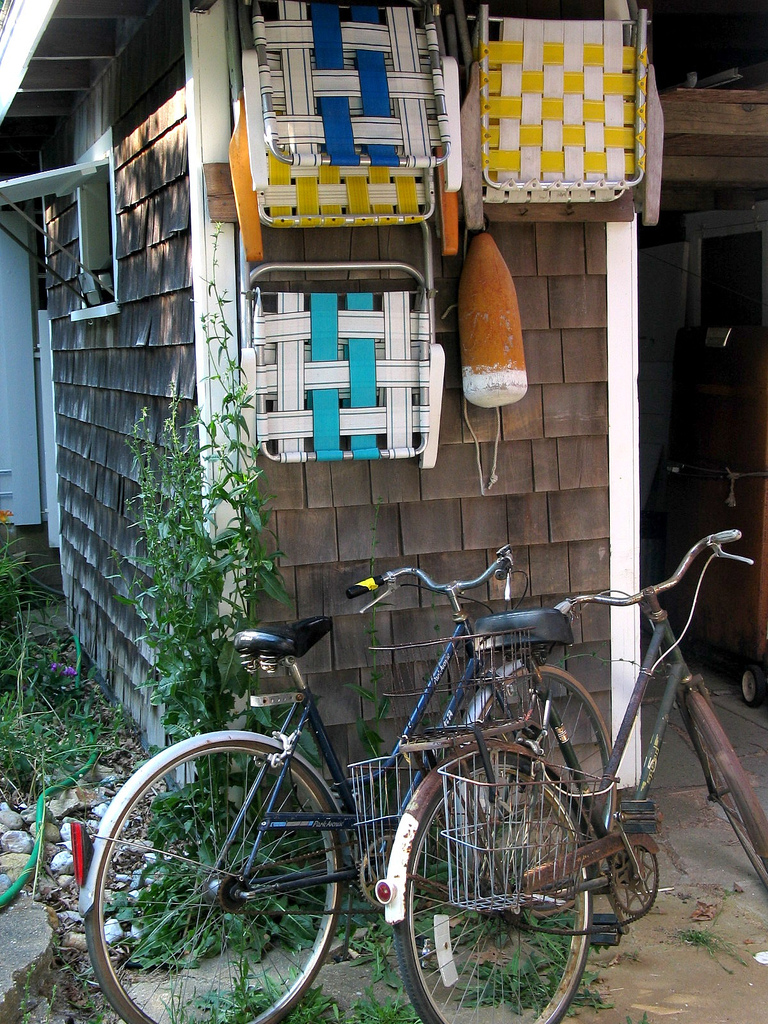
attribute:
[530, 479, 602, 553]
siding — wood, brown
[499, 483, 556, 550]
siding — brown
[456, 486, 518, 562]
siding — brown, wood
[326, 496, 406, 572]
siding — wood, brown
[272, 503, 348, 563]
siding — wood, brown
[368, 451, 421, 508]
siding — brown, wood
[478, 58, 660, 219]
chair — yellow, white, beach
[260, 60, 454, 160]
chair — beach, dark blue, white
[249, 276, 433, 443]
chair — beach, light, blue, white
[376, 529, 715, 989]
bicycle — old, rusty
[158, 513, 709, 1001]
handle — black, yellow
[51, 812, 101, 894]
light — red, black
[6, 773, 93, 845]
hose — yellow, green, water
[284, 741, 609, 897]
racks — wire, bicycle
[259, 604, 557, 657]
seats — black, bicycle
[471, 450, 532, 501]
shingle — wood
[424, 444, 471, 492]
shingle — wood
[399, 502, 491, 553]
shingle — wood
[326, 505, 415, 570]
shingle — wood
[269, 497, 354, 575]
shingle — wood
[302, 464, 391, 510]
shingle — wood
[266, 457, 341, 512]
shingle — wood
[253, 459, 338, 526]
shingle — wood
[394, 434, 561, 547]
shingle — wood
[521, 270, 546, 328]
shingle — wood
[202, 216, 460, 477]
chair — white, teal, lawn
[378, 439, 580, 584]
house — white, yellow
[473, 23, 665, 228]
chair — lawn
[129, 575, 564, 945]
bike — blue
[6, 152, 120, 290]
window — open